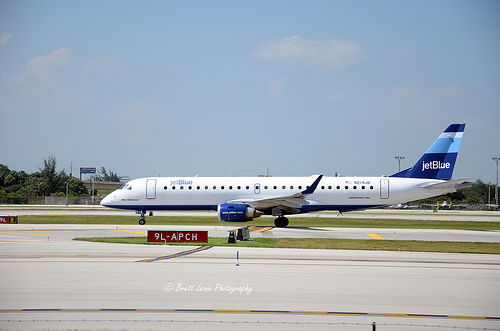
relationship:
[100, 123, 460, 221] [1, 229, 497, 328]
airplane on ground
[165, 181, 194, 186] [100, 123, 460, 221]
name on airplane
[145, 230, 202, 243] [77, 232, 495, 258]
sign on grass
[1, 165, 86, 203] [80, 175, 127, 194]
trees next to building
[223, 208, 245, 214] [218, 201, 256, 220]
white writing on blue engine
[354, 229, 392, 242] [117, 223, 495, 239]
yellow lines on grey pavement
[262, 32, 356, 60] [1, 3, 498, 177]
clouds in sky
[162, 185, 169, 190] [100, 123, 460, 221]
window on side of airplane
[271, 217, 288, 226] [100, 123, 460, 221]
wheel on airplane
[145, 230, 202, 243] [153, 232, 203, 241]
sign with white letters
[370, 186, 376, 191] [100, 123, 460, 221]
window on airplane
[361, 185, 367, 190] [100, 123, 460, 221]
window on airplane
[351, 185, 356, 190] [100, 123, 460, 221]
window on airplane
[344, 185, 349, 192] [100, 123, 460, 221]
window on side of airplane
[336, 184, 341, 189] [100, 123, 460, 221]
window on airplane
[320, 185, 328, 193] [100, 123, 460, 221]
window on airplane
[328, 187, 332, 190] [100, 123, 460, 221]
window on airplane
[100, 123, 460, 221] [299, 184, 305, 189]
airplane with window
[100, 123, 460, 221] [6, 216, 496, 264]
airplane on runway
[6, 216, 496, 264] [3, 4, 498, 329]
runway at airport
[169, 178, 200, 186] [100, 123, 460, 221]
jetblue written on airplane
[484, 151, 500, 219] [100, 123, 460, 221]
light pole next to airplane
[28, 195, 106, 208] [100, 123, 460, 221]
fence behind airplane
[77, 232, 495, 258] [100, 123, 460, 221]
grass in front of airplane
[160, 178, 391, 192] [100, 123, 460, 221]
windows on airplane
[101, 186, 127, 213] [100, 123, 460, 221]
nose of airplane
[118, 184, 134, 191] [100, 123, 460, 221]
cockpit windows on airplane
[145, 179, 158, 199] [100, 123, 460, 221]
door on airplane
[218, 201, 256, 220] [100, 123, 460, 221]
engine of airplane